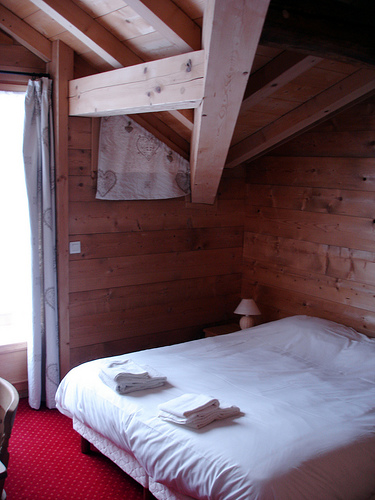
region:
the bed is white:
[248, 351, 351, 492]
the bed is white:
[265, 374, 313, 475]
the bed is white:
[291, 332, 336, 488]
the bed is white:
[238, 339, 272, 498]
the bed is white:
[276, 407, 322, 493]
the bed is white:
[275, 436, 297, 481]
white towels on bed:
[148, 382, 238, 442]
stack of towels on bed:
[90, 342, 185, 407]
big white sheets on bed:
[216, 334, 334, 481]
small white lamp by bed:
[233, 286, 272, 333]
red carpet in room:
[11, 437, 110, 498]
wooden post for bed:
[64, 420, 103, 465]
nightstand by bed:
[196, 319, 235, 338]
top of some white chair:
[4, 383, 31, 434]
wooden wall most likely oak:
[259, 259, 361, 307]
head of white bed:
[275, 302, 368, 368]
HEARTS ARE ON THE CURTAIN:
[93, 161, 133, 200]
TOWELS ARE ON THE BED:
[102, 355, 240, 444]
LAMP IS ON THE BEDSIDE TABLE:
[233, 292, 274, 330]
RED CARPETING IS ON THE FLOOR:
[6, 397, 119, 491]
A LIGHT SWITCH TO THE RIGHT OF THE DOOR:
[53, 236, 85, 255]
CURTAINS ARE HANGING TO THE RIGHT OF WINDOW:
[20, 71, 68, 412]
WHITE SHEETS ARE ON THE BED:
[50, 308, 373, 495]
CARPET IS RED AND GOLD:
[1, 394, 146, 492]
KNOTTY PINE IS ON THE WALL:
[100, 224, 261, 280]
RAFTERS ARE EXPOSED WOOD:
[58, 26, 276, 201]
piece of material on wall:
[93, 125, 183, 222]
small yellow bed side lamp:
[243, 282, 265, 344]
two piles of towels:
[101, 359, 244, 459]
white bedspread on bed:
[97, 349, 368, 478]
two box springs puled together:
[69, 414, 187, 497]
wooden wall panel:
[150, 209, 347, 279]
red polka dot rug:
[29, 443, 80, 499]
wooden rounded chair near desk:
[6, 386, 28, 454]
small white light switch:
[60, 228, 99, 270]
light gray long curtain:
[25, 83, 67, 404]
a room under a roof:
[6, 12, 362, 497]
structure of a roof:
[4, 3, 374, 207]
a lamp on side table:
[227, 290, 265, 336]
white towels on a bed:
[149, 382, 246, 437]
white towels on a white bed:
[87, 348, 173, 402]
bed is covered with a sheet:
[47, 309, 371, 498]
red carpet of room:
[8, 404, 112, 498]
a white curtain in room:
[17, 70, 71, 416]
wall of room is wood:
[78, 130, 371, 299]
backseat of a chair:
[0, 369, 23, 490]